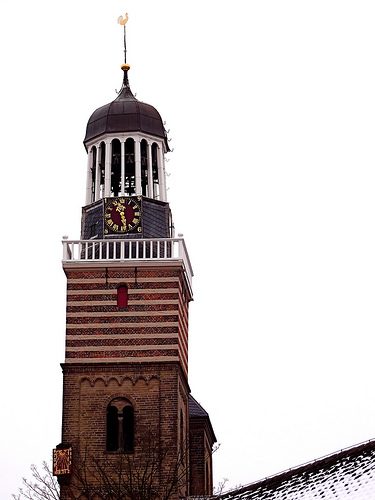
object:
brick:
[80, 433, 91, 438]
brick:
[159, 403, 166, 406]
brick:
[144, 398, 151, 401]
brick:
[139, 397, 148, 403]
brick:
[94, 416, 100, 421]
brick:
[168, 459, 178, 464]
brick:
[145, 405, 156, 410]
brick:
[68, 390, 76, 396]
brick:
[170, 370, 175, 378]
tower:
[53, 12, 217, 497]